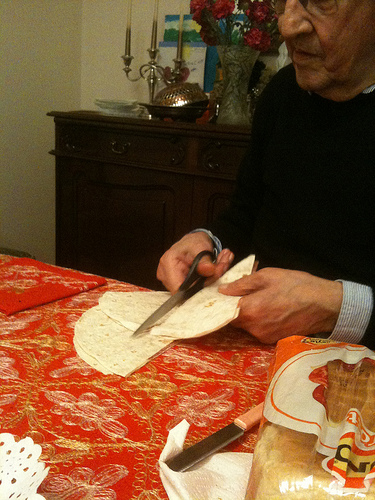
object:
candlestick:
[125, 1, 131, 56]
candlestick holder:
[120, 47, 185, 119]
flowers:
[244, 28, 262, 45]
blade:
[164, 422, 244, 474]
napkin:
[157, 419, 255, 500]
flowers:
[253, 30, 270, 51]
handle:
[110, 142, 131, 154]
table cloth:
[0, 251, 375, 500]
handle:
[233, 400, 265, 433]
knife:
[163, 400, 271, 472]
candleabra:
[120, 0, 183, 118]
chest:
[45, 94, 348, 300]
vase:
[215, 44, 260, 125]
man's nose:
[277, 0, 312, 38]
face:
[277, 3, 375, 95]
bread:
[238, 335, 373, 498]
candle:
[151, 1, 158, 48]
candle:
[177, 0, 183, 57]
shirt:
[194, 63, 375, 351]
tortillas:
[72, 305, 175, 379]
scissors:
[131, 250, 218, 340]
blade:
[128, 290, 181, 337]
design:
[44, 389, 128, 439]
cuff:
[324, 279, 374, 355]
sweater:
[191, 66, 375, 351]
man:
[156, 0, 375, 346]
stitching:
[125, 438, 146, 449]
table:
[0, 253, 374, 500]